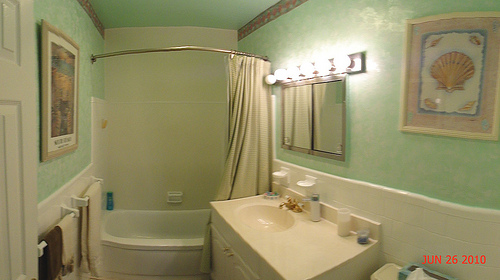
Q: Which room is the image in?
A: It is at the bathroom.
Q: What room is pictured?
A: It is a bathroom.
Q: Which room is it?
A: It is a bathroom.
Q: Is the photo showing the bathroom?
A: Yes, it is showing the bathroom.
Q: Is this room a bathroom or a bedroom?
A: It is a bathroom.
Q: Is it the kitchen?
A: No, it is the bathroom.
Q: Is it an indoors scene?
A: Yes, it is indoors.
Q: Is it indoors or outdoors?
A: It is indoors.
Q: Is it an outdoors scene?
A: No, it is indoors.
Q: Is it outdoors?
A: No, it is indoors.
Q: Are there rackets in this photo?
A: No, there are no rackets.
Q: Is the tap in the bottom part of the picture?
A: Yes, the tap is in the bottom of the image.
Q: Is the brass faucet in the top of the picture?
A: No, the faucet is in the bottom of the image.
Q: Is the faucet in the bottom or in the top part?
A: The faucet is in the bottom of the image.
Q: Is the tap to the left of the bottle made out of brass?
A: Yes, the faucet is made of brass.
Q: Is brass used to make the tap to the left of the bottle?
A: Yes, the faucet is made of brass.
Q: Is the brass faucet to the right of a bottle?
A: No, the tap is to the left of a bottle.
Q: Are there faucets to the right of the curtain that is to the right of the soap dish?
A: Yes, there is a faucet to the right of the curtain.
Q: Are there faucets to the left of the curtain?
A: No, the faucet is to the right of the curtain.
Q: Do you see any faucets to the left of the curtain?
A: No, the faucet is to the right of the curtain.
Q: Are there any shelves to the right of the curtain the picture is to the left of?
A: No, there is a faucet to the right of the curtain.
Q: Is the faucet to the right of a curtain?
A: Yes, the faucet is to the right of a curtain.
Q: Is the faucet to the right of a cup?
A: No, the faucet is to the right of a curtain.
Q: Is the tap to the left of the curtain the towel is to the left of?
A: No, the tap is to the right of the curtain.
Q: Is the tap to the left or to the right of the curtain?
A: The tap is to the right of the curtain.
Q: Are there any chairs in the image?
A: No, there are no chairs.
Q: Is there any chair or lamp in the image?
A: No, there are no chairs or lamps.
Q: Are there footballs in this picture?
A: No, there are no footballs.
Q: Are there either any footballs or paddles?
A: No, there are no footballs or paddles.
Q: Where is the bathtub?
A: The bathtub is in the bathroom.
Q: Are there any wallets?
A: No, there are no wallets.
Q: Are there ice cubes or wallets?
A: No, there are no wallets or ice cubes.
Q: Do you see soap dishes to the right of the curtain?
A: Yes, there is a soap dish to the right of the curtain.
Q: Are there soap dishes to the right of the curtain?
A: Yes, there is a soap dish to the right of the curtain.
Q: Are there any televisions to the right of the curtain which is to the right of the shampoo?
A: No, there is a soap dish to the right of the curtain.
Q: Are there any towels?
A: Yes, there is a towel.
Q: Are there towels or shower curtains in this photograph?
A: Yes, there is a towel.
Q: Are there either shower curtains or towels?
A: Yes, there is a towel.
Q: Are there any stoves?
A: No, there are no stoves.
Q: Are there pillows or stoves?
A: No, there are no stoves or pillows.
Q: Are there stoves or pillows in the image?
A: No, there are no stoves or pillows.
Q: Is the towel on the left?
A: Yes, the towel is on the left of the image.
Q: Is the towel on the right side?
A: No, the towel is on the left of the image.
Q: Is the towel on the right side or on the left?
A: The towel is on the left of the image.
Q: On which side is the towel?
A: The towel is on the left of the image.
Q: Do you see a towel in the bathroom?
A: Yes, there is a towel in the bathroom.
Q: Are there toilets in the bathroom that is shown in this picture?
A: No, there is a towel in the bathroom.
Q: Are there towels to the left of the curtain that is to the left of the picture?
A: Yes, there is a towel to the left of the curtain.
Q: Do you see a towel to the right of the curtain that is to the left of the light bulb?
A: No, the towel is to the left of the curtain.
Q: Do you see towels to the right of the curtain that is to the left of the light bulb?
A: No, the towel is to the left of the curtain.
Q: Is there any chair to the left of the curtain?
A: No, there is a towel to the left of the curtain.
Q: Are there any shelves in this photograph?
A: No, there are no shelves.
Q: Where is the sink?
A: The sink is in the bathroom.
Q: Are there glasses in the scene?
A: No, there are no glasses.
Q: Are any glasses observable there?
A: No, there are no glasses.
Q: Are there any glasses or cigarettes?
A: No, there are no glasses or cigarettes.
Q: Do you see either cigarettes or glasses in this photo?
A: No, there are no glasses or cigarettes.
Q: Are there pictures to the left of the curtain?
A: Yes, there is a picture to the left of the curtain.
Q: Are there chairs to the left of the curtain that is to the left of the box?
A: No, there is a picture to the left of the curtain.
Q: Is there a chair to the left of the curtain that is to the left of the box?
A: No, there is a picture to the left of the curtain.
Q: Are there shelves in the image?
A: No, there are no shelves.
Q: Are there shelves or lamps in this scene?
A: No, there are no shelves or lamps.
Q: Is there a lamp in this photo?
A: No, there are no lamps.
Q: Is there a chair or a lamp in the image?
A: No, there are no lamps or chairs.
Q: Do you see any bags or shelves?
A: No, there are no shelves or bags.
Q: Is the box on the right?
A: Yes, the box is on the right of the image.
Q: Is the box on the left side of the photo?
A: No, the box is on the right of the image.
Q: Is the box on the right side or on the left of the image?
A: The box is on the right of the image.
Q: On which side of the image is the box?
A: The box is on the right of the image.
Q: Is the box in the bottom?
A: Yes, the box is in the bottom of the image.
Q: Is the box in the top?
A: No, the box is in the bottom of the image.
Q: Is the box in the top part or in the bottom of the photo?
A: The box is in the bottom of the image.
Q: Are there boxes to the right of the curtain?
A: Yes, there is a box to the right of the curtain.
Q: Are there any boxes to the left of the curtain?
A: No, the box is to the right of the curtain.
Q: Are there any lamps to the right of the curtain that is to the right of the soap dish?
A: No, there is a box to the right of the curtain.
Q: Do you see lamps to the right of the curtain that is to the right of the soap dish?
A: No, there is a box to the right of the curtain.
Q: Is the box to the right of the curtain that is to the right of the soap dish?
A: Yes, the box is to the right of the curtain.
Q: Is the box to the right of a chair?
A: No, the box is to the right of the curtain.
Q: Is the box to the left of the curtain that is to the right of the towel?
A: No, the box is to the right of the curtain.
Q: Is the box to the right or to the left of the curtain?
A: The box is to the right of the curtain.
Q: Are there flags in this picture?
A: No, there are no flags.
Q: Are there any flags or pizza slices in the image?
A: No, there are no flags or pizza slices.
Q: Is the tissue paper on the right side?
A: Yes, the tissue paper is on the right of the image.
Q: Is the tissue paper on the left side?
A: No, the tissue paper is on the right of the image.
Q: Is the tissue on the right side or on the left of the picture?
A: The tissue is on the right of the image.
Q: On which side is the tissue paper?
A: The tissue paper is on the right of the image.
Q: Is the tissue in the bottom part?
A: Yes, the tissue is in the bottom of the image.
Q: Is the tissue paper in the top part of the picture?
A: No, the tissue paper is in the bottom of the image.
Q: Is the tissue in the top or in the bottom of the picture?
A: The tissue is in the bottom of the image.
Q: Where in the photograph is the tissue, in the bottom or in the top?
A: The tissue is in the bottom of the image.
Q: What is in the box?
A: The tissue is in the box.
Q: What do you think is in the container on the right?
A: The tissue is in the box.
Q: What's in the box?
A: The tissue is in the box.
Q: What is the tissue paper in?
A: The tissue paper is in the box.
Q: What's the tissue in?
A: The tissue paper is in the box.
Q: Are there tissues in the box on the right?
A: Yes, there is a tissue in the box.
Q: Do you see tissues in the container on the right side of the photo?
A: Yes, there is a tissue in the box.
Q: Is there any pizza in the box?
A: No, there is a tissue in the box.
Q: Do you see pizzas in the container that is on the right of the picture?
A: No, there is a tissue in the box.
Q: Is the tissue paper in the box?
A: Yes, the tissue paper is in the box.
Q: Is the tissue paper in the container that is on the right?
A: Yes, the tissue paper is in the box.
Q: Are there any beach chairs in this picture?
A: No, there are no beach chairs.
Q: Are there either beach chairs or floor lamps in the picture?
A: No, there are no beach chairs or floor lamps.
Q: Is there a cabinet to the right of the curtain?
A: No, there is a soap dish to the right of the curtain.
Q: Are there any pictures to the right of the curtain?
A: Yes, there is a picture to the right of the curtain.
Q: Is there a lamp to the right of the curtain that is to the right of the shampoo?
A: No, there is a picture to the right of the curtain.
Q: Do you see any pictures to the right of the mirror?
A: Yes, there is a picture to the right of the mirror.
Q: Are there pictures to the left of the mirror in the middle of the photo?
A: No, the picture is to the right of the mirror.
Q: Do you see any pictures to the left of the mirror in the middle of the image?
A: No, the picture is to the right of the mirror.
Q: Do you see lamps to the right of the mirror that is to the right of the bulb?
A: No, there is a picture to the right of the mirror.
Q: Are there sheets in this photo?
A: No, there are no sheets.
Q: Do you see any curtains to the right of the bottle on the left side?
A: Yes, there is a curtain to the right of the bottle.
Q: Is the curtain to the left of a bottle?
A: No, the curtain is to the right of a bottle.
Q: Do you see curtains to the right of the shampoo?
A: Yes, there is a curtain to the right of the shampoo.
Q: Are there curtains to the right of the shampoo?
A: Yes, there is a curtain to the right of the shampoo.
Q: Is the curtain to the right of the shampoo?
A: Yes, the curtain is to the right of the shampoo.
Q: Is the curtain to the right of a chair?
A: No, the curtain is to the right of the shampoo.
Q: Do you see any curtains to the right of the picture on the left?
A: Yes, there is a curtain to the right of the picture.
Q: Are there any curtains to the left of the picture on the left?
A: No, the curtain is to the right of the picture.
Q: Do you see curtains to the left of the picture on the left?
A: No, the curtain is to the right of the picture.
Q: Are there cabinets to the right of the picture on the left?
A: No, there is a curtain to the right of the picture.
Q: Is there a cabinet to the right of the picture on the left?
A: No, there is a curtain to the right of the picture.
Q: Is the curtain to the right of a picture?
A: Yes, the curtain is to the right of a picture.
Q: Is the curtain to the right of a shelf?
A: No, the curtain is to the right of a picture.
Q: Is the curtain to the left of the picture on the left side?
A: No, the curtain is to the right of the picture.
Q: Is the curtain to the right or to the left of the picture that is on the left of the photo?
A: The curtain is to the right of the picture.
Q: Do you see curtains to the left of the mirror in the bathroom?
A: Yes, there is a curtain to the left of the mirror.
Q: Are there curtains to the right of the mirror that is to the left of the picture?
A: No, the curtain is to the left of the mirror.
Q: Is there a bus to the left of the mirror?
A: No, there is a curtain to the left of the mirror.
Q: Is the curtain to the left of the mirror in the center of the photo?
A: Yes, the curtain is to the left of the mirror.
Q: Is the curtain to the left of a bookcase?
A: No, the curtain is to the left of the mirror.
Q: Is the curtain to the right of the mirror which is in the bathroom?
A: No, the curtain is to the left of the mirror.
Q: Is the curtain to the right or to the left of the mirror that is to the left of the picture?
A: The curtain is to the left of the mirror.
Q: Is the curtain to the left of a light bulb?
A: Yes, the curtain is to the left of a light bulb.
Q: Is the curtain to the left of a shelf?
A: No, the curtain is to the left of a light bulb.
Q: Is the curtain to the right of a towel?
A: Yes, the curtain is to the right of a towel.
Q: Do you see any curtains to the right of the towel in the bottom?
A: Yes, there is a curtain to the right of the towel.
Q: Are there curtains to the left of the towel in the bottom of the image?
A: No, the curtain is to the right of the towel.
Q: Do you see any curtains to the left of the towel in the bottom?
A: No, the curtain is to the right of the towel.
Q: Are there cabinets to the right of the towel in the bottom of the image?
A: No, there is a curtain to the right of the towel.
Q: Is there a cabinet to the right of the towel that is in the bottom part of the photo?
A: No, there is a curtain to the right of the towel.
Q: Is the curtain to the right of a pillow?
A: No, the curtain is to the right of a towel.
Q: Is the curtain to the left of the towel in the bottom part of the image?
A: No, the curtain is to the right of the towel.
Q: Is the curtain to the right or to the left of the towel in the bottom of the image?
A: The curtain is to the right of the towel.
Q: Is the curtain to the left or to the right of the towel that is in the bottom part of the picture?
A: The curtain is to the right of the towel.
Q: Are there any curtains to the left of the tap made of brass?
A: Yes, there is a curtain to the left of the faucet.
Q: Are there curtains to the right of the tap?
A: No, the curtain is to the left of the tap.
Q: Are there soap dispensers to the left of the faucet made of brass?
A: No, there is a curtain to the left of the tap.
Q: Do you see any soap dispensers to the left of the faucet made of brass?
A: No, there is a curtain to the left of the tap.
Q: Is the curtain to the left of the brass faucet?
A: Yes, the curtain is to the left of the faucet.